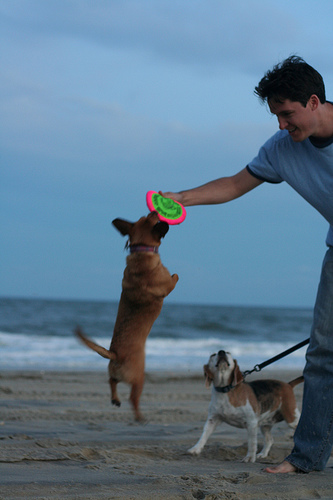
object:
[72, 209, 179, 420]
dog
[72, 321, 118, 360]
tail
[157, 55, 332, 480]
guy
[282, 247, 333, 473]
pant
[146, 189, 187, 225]
frisbee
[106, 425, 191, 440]
track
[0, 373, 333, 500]
sand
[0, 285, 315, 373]
water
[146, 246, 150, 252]
blue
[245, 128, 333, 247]
shirt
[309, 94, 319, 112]
ear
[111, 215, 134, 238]
ear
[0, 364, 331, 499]
beach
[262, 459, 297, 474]
foot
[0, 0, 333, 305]
sky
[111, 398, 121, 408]
paw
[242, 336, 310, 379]
leash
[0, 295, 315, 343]
ocean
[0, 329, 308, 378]
wave